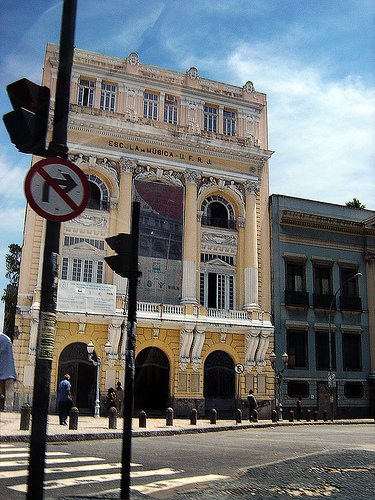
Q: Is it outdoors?
A: Yes, it is outdoors.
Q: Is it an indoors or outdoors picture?
A: It is outdoors.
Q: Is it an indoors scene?
A: No, it is outdoors.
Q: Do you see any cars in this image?
A: No, there are no cars.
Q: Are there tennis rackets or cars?
A: No, there are no cars or tennis rackets.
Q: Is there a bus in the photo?
A: No, there are no buses.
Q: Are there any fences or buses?
A: No, there are no buses or fences.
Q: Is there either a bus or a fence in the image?
A: No, there are no fences or buses.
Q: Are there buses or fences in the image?
A: No, there are no fences or buses.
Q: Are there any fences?
A: No, there are no fences.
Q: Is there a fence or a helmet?
A: No, there are no fences or helmets.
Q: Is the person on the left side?
A: Yes, the person is on the left of the image.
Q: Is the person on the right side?
A: No, the person is on the left of the image.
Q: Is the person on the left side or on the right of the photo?
A: The person is on the left of the image.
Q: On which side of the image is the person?
A: The person is on the left of the image.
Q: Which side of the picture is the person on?
A: The person is on the left of the image.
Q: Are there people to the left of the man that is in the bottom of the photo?
A: Yes, there is a person to the left of the man.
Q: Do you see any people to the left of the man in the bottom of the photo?
A: Yes, there is a person to the left of the man.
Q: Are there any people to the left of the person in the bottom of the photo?
A: Yes, there is a person to the left of the man.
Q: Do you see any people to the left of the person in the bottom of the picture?
A: Yes, there is a person to the left of the man.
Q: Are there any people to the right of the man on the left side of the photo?
A: No, the person is to the left of the man.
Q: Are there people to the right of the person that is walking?
A: No, the person is to the left of the man.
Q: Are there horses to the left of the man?
A: No, there is a person to the left of the man.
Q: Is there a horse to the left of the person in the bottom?
A: No, there is a person to the left of the man.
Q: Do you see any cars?
A: No, there are no cars.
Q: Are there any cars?
A: No, there are no cars.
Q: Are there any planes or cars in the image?
A: No, there are no cars or planes.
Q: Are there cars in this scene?
A: No, there are no cars.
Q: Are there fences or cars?
A: No, there are no cars or fences.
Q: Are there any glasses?
A: No, there are no glasses.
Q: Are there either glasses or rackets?
A: No, there are no glasses or rackets.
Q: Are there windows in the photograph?
A: Yes, there is a window.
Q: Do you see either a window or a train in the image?
A: Yes, there is a window.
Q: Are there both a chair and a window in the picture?
A: No, there is a window but no chairs.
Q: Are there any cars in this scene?
A: No, there are no cars.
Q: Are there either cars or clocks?
A: No, there are no cars or clocks.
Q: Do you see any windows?
A: Yes, there is a window.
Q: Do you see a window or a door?
A: Yes, there is a window.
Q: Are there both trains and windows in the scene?
A: No, there is a window but no trains.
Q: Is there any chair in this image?
A: No, there are no chairs.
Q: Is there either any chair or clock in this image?
A: No, there are no chairs or clocks.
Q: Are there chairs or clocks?
A: No, there are no chairs or clocks.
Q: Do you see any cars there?
A: No, there are no cars.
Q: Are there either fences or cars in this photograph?
A: No, there are no cars or fences.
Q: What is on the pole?
A: The sign is on the pole.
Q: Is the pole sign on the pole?
A: Yes, the sign is on the pole.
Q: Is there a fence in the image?
A: No, there are no fences.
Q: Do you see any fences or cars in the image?
A: No, there are no fences or cars.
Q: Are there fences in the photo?
A: No, there are no fences.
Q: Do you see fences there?
A: No, there are no fences.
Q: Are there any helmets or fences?
A: No, there are no fences or helmets.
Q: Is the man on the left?
A: Yes, the man is on the left of the image.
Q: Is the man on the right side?
A: No, the man is on the left of the image.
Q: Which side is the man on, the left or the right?
A: The man is on the left of the image.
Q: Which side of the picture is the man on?
A: The man is on the left of the image.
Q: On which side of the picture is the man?
A: The man is on the left of the image.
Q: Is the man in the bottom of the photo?
A: Yes, the man is in the bottom of the image.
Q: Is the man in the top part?
A: No, the man is in the bottom of the image.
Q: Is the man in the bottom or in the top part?
A: The man is in the bottom of the image.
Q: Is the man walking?
A: Yes, the man is walking.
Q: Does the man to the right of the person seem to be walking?
A: Yes, the man is walking.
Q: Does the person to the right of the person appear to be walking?
A: Yes, the man is walking.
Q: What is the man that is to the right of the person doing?
A: The man is walking.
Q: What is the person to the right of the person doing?
A: The man is walking.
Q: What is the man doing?
A: The man is walking.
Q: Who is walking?
A: The man is walking.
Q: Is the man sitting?
A: No, the man is walking.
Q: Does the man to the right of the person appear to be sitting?
A: No, the man is walking.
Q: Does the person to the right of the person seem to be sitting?
A: No, the man is walking.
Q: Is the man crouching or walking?
A: The man is walking.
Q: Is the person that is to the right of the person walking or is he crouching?
A: The man is walking.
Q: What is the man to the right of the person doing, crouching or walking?
A: The man is walking.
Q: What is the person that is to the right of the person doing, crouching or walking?
A: The man is walking.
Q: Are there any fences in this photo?
A: No, there are no fences.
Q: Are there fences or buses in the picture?
A: No, there are no fences or buses.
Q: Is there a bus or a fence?
A: No, there are no fences or buses.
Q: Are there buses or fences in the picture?
A: No, there are no fences or buses.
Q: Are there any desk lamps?
A: No, there are no desk lamps.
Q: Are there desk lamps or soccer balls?
A: No, there are no desk lamps or soccer balls.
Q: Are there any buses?
A: No, there are no buses.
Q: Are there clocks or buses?
A: No, there are no buses or clocks.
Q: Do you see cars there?
A: No, there are no cars.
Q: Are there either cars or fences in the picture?
A: No, there are no cars or fences.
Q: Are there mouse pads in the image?
A: No, there are no mouse pads.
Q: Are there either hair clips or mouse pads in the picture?
A: No, there are no mouse pads or hair clips.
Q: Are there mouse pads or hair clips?
A: No, there are no mouse pads or hair clips.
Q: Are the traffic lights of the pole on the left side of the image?
A: Yes, the traffic lights are on the left of the image.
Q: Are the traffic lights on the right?
A: No, the traffic lights are on the left of the image.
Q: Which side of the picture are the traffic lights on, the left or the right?
A: The traffic lights are on the left of the image.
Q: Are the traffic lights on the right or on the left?
A: The traffic lights are on the left of the image.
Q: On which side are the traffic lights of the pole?
A: The traffic lights are on the left of the image.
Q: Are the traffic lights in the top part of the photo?
A: Yes, the traffic lights are in the top of the image.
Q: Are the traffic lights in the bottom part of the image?
A: No, the traffic lights are in the top of the image.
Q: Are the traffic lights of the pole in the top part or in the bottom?
A: The traffic lights are in the top of the image.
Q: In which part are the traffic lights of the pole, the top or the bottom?
A: The traffic lights are in the top of the image.